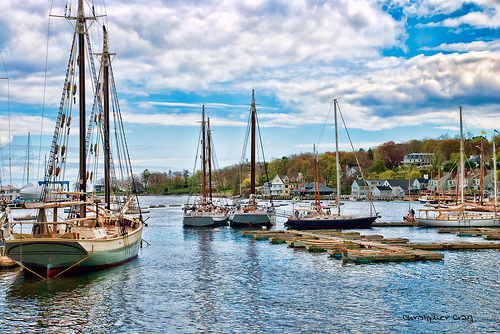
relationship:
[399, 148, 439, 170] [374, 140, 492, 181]
house on hill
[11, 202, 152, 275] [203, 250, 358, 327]
boat on harbor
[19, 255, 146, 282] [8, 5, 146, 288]
red bottom on boat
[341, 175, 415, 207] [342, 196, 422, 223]
buildings on shore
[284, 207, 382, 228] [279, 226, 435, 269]
boat near a dock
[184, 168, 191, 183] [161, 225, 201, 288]
tree beside a lake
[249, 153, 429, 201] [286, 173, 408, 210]
tree and houses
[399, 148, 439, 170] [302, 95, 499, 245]
house overlooking boats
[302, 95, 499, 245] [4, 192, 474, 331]
boats in harbor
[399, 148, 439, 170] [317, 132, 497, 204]
house on hill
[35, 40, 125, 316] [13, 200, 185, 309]
sailboat on water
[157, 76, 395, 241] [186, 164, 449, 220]
boats in harbor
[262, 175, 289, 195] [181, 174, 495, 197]
house in shore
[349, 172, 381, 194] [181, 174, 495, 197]
house in shore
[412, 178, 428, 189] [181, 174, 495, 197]
house in shore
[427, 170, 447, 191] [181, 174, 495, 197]
house in shore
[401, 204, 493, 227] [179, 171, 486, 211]
boat in harbor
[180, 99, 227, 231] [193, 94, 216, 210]
boat has mast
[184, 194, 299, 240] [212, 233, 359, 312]
boats on water